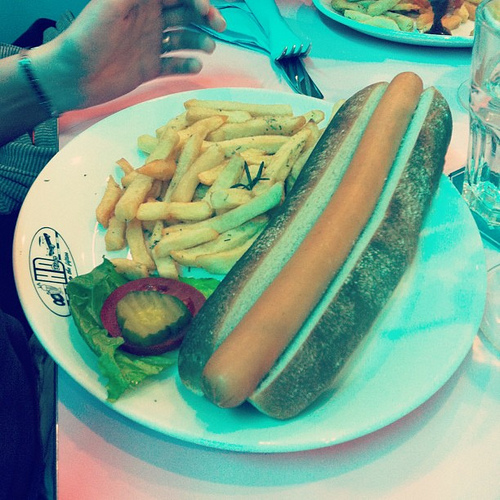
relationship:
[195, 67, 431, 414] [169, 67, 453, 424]
hotdog inside bun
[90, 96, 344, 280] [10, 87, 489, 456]
french fries on top of plate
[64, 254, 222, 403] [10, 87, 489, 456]
lettuce on top of plate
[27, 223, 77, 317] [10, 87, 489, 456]
logo painted onto plate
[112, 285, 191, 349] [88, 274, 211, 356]
pickle sitting on tomato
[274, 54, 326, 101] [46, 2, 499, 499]
knife on top of table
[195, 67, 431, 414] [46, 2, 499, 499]
hotdog on top of table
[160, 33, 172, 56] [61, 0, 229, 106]
wedding band on top of hand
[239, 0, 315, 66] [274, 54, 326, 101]
fork on top of knife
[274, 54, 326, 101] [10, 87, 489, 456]
knife near plate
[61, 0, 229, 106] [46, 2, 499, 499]
hand above table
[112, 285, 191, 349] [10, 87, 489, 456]
pickle on top of plate